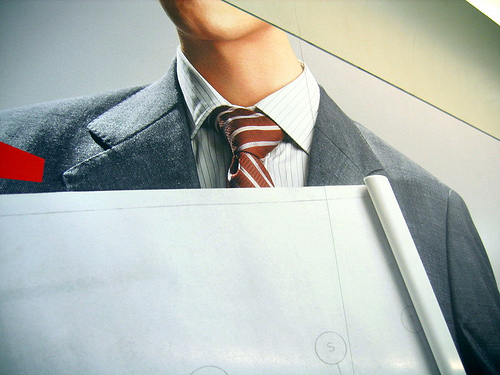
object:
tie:
[205, 105, 285, 187]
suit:
[1, 55, 500, 374]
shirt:
[177, 46, 322, 186]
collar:
[175, 46, 321, 156]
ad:
[2, 1, 499, 374]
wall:
[224, 1, 499, 141]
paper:
[1, 175, 467, 374]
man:
[1, 1, 500, 374]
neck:
[180, 27, 303, 106]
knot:
[204, 104, 288, 159]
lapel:
[61, 57, 201, 190]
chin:
[160, 1, 265, 41]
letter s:
[324, 340, 336, 352]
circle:
[315, 331, 347, 364]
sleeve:
[447, 189, 500, 375]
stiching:
[317, 126, 366, 175]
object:
[1, 142, 45, 182]